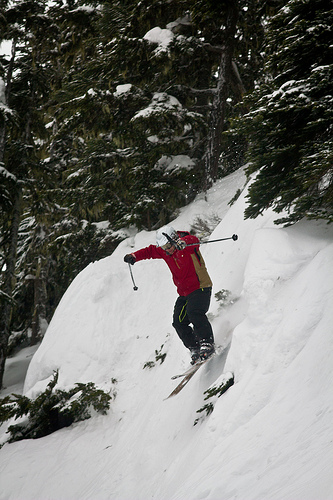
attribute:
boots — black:
[182, 335, 216, 365]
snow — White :
[0, 161, 330, 498]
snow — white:
[243, 310, 328, 498]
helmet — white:
[151, 222, 171, 252]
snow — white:
[259, 234, 290, 275]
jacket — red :
[130, 230, 214, 294]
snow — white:
[161, 387, 199, 409]